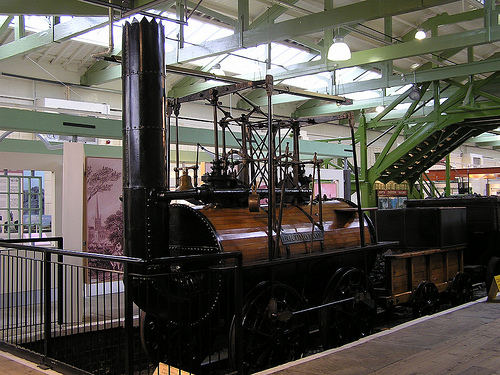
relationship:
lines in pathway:
[292, 349, 329, 364] [394, 346, 429, 361]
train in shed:
[116, 194, 471, 314] [166, 76, 323, 158]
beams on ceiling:
[407, 22, 484, 118] [187, 0, 268, 30]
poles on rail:
[153, 298, 190, 355] [95, 252, 129, 262]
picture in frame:
[91, 182, 117, 209] [77, 157, 132, 284]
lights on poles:
[329, 44, 352, 57] [153, 298, 190, 355]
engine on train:
[250, 270, 334, 316] [116, 194, 471, 314]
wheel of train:
[246, 278, 276, 353] [116, 194, 471, 314]